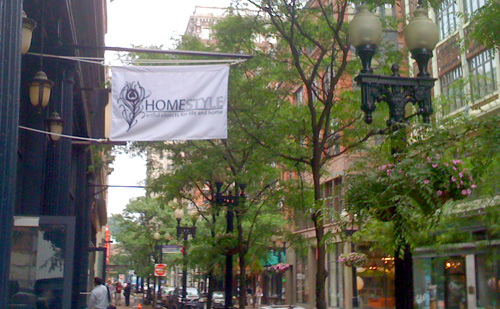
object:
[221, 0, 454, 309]
trees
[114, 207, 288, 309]
walkway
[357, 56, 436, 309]
lamppost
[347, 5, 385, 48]
bulbs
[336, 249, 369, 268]
basket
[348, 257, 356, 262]
flowers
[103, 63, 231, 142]
banner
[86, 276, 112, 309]
person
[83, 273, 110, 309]
door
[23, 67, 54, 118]
fixtures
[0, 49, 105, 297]
front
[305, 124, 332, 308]
trunk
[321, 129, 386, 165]
branches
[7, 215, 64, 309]
door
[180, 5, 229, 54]
building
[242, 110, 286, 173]
leaves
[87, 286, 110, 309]
shirt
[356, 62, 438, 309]
pole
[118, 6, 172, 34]
sky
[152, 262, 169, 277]
sign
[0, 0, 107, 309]
building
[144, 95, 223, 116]
writing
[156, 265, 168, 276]
writing